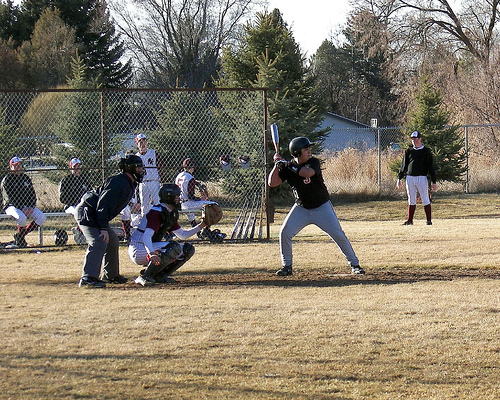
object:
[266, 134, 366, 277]
player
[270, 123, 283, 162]
bat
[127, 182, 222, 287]
catcher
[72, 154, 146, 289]
umpire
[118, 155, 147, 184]
helmet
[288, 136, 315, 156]
helmet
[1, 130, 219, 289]
people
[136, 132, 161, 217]
player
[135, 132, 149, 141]
hat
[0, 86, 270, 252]
fence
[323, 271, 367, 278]
base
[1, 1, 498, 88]
sky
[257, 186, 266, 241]
bats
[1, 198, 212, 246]
dugout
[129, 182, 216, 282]
guards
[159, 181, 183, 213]
mask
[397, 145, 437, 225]
uniform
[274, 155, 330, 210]
shirt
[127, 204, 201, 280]
uniform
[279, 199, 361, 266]
pants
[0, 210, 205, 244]
bench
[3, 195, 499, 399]
field